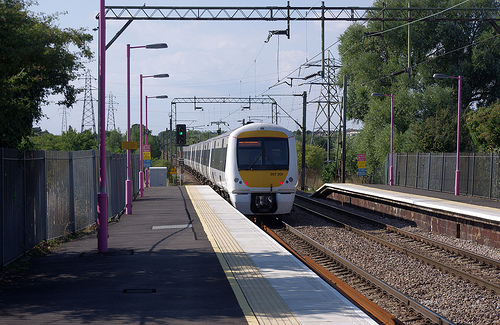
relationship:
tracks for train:
[156, 144, 499, 324] [178, 117, 305, 224]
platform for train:
[181, 181, 385, 324] [178, 117, 305, 224]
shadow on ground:
[1, 244, 342, 322] [1, 178, 246, 324]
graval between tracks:
[282, 200, 495, 323] [156, 144, 499, 324]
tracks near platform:
[156, 144, 499, 324] [181, 181, 385, 324]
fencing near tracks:
[0, 147, 157, 270] [156, 144, 499, 324]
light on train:
[244, 180, 254, 188] [178, 117, 305, 224]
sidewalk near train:
[1, 178, 246, 324] [178, 117, 305, 224]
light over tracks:
[368, 85, 403, 187] [156, 144, 499, 324]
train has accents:
[178, 117, 305, 224] [235, 125, 289, 190]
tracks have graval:
[156, 144, 499, 324] [282, 200, 495, 323]